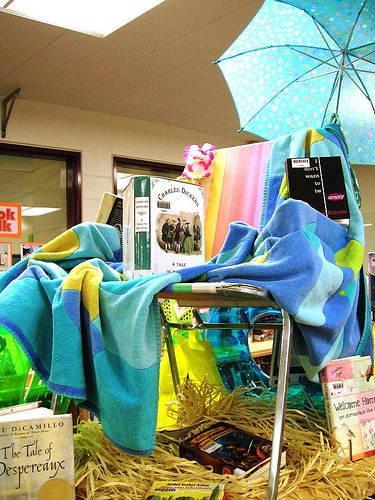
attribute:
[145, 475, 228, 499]
book — yellow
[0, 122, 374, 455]
towel — blue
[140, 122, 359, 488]
chair — striped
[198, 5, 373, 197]
umbrella — blue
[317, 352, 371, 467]
book — orange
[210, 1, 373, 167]
umbrella — blue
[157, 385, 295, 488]
book — pink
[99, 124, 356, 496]
chair — beach, small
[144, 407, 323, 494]
straw — piled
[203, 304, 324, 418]
innertube — blown up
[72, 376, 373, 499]
hay — displayed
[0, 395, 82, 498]
book — open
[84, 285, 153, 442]
towel — blue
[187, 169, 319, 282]
towel — blue, green, beach towel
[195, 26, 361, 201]
umbrella — open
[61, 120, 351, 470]
chair — yellow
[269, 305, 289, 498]
leg — metal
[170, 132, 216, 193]
lei — flowered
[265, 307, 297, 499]
leg — silver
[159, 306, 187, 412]
leg — silver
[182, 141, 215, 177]
flower — purple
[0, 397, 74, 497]
cover — tan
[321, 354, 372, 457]
cover — pink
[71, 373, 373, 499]
straw — yellow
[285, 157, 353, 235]
book — black